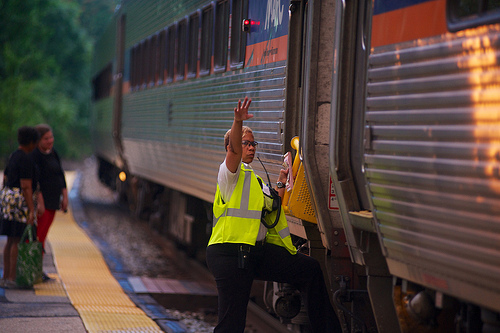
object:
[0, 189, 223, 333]
ground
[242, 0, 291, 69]
advertising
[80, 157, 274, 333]
gray gravel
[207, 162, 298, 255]
green vest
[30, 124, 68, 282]
woman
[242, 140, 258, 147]
glasses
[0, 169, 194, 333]
platform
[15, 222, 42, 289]
bag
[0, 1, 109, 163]
green trees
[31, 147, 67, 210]
shirt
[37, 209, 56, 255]
pants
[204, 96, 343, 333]
woman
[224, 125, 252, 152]
hair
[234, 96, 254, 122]
hand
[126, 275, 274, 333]
walkway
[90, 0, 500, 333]
car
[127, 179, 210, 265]
wheels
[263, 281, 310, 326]
wheels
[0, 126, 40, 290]
woman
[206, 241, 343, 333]
pants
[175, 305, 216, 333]
pebbles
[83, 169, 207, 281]
rocks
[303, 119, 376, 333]
stairs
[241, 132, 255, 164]
face